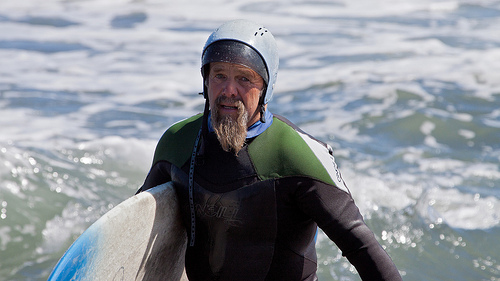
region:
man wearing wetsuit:
[136, 17, 406, 279]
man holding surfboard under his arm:
[46, 15, 403, 280]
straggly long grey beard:
[212, 110, 246, 156]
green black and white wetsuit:
[126, 108, 406, 279]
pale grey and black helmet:
[201, 15, 281, 108]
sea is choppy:
[1, 1, 499, 278]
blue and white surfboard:
[47, 182, 187, 279]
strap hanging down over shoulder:
[184, 101, 208, 251]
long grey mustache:
[211, 96, 245, 122]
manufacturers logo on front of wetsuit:
[181, 200, 241, 220]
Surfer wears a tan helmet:
[121, 14, 413, 279]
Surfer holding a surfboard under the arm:
[29, 7, 423, 279]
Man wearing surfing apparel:
[117, 14, 424, 279]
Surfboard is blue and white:
[37, 167, 215, 279]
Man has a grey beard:
[126, 5, 413, 277]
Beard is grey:
[205, 93, 252, 158]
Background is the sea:
[3, 8, 498, 276]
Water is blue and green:
[7, 10, 497, 278]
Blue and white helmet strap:
[174, 85, 219, 248]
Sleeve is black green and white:
[279, 122, 406, 279]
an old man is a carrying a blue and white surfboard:
[114, 17, 345, 279]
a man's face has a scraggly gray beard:
[206, 51, 274, 153]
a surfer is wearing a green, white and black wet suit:
[151, 21, 350, 276]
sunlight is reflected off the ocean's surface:
[4, 140, 120, 195]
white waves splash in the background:
[371, 179, 498, 234]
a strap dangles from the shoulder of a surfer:
[191, 114, 198, 249]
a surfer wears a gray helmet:
[151, 10, 370, 279]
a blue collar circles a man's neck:
[251, 123, 271, 139]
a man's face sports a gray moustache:
[199, 66, 264, 132]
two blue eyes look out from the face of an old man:
[201, 60, 263, 148]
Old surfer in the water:
[128, 17, 416, 279]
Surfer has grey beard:
[142, 13, 399, 279]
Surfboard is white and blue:
[35, 155, 190, 275]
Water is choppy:
[3, 3, 494, 278]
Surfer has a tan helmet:
[128, 13, 426, 278]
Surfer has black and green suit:
[126, 3, 421, 278]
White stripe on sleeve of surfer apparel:
[293, 122, 348, 200]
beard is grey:
[201, 90, 252, 155]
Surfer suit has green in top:
[131, 111, 412, 278]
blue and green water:
[5, 7, 498, 254]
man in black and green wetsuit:
[57, 12, 401, 279]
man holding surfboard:
[40, 18, 431, 271]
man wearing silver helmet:
[32, 12, 411, 272]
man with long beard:
[195, 17, 282, 154]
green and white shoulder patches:
[260, 115, 350, 209]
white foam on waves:
[29, 12, 494, 193]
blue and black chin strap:
[175, 109, 210, 246]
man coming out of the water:
[17, 9, 414, 277]